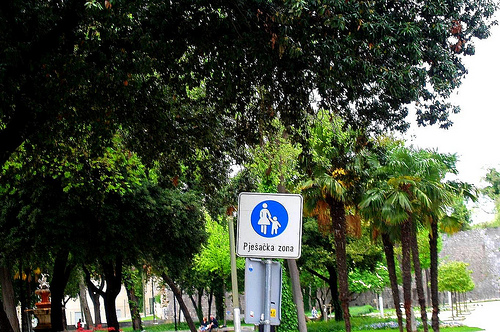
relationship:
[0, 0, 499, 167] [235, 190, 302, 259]
tree overlooking sign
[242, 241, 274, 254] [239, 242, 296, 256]
word written polish language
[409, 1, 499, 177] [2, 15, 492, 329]
sky over trees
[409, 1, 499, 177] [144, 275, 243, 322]
sky over building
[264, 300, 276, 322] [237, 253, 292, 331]
stickers on sign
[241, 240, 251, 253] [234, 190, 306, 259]
letters on sign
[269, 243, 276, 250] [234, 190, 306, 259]
letters on sign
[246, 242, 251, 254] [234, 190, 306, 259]
letters on sign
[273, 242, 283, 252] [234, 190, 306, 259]
letters on sign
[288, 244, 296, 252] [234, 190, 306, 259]
letters on sign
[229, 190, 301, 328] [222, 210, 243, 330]
signs on pole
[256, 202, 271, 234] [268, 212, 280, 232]
lady hold child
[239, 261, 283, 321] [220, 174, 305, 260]
stickers on sign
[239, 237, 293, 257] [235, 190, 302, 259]
letters on a sign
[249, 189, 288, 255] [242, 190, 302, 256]
circle on sign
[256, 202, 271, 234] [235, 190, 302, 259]
lady and child on a sign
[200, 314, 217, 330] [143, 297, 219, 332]
people sitting on a bench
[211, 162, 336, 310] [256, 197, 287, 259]
sign depicts an adult and child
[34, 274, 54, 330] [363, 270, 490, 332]
fountain made of stone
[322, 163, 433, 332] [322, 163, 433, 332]
tall trees are tall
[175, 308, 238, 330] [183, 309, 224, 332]
people are relaxing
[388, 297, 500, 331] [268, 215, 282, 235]
road sign with a lady and child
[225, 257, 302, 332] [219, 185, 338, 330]
box under road sign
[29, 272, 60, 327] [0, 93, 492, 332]
water fountain in park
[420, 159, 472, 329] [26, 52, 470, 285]
palm tree in distance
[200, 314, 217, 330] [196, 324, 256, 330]
people sitting on a park bench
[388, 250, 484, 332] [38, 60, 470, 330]
road adjacent to park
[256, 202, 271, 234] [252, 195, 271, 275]
lady representing lady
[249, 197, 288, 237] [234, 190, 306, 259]
blue circle symbol on sign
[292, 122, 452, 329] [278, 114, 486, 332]
palms in back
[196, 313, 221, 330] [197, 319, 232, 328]
people seated in bench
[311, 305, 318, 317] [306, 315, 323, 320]
woman seated in bench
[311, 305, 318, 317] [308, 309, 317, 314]
woman wearing t-shirt